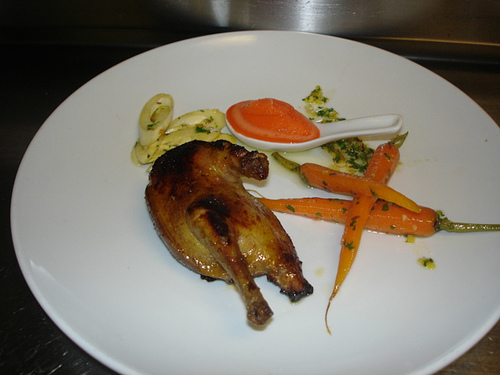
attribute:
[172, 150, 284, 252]
chicken — some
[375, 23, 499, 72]
table — brown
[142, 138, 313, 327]
thigh — part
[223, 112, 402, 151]
spoon — short, white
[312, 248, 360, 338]
tip — part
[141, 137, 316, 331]
meat — oily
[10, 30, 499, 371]
dish — wide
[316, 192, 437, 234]
carrot — orange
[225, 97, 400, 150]
spoon — white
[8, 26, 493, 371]
plate — white, edge, clean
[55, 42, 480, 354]
plate — round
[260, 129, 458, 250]
carrots — these, some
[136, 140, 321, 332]
chicken — cooked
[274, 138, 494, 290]
carrot — orange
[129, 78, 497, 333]
foods — different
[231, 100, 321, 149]
food stuff — orange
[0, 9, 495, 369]
table — dark , black, wooden, wood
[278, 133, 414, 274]
sprinklings — green, vegetable